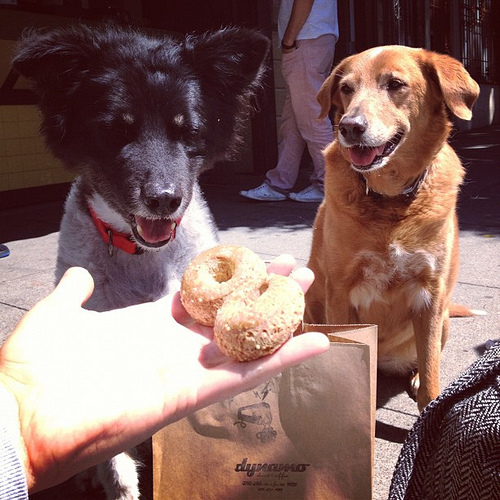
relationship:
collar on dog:
[86, 192, 146, 264] [5, 26, 255, 302]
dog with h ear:
[300, 44, 485, 412] [418, 47, 482, 127]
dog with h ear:
[300, 44, 485, 412] [312, 55, 342, 124]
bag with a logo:
[145, 322, 380, 498] [232, 401, 277, 444]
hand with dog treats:
[0, 249, 330, 486] [176, 233, 309, 365]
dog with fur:
[299, 41, 490, 426] [318, 147, 463, 389]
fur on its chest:
[318, 147, 463, 389] [349, 227, 452, 340]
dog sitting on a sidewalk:
[300, 44, 485, 412] [2, 147, 499, 499]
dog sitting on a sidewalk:
[0, 0, 229, 500] [2, 147, 499, 499]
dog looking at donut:
[1, 25, 225, 499] [212, 274, 309, 364]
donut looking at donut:
[172, 231, 312, 375] [180, 243, 264, 318]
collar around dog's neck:
[85, 201, 144, 256] [72, 160, 129, 230]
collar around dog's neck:
[359, 166, 430, 204] [358, 122, 451, 196]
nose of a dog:
[127, 171, 220, 224] [5, 26, 255, 302]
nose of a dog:
[333, 121, 376, 153] [320, 48, 467, 381]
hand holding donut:
[0, 249, 330, 486] [215, 276, 319, 361]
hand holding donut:
[0, 249, 330, 486] [176, 242, 265, 327]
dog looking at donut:
[300, 44, 485, 412] [176, 242, 265, 327]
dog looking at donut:
[300, 44, 485, 412] [212, 274, 309, 364]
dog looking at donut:
[0, 0, 229, 500] [176, 242, 265, 327]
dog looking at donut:
[0, 0, 229, 500] [210, 272, 318, 358]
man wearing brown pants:
[238, 0, 336, 202] [260, 32, 340, 200]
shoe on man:
[286, 184, 323, 206] [245, 2, 350, 218]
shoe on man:
[239, 184, 285, 204] [245, 2, 350, 218]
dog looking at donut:
[0, 0, 229, 500] [212, 274, 309, 364]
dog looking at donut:
[0, 0, 229, 500] [172, 243, 270, 329]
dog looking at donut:
[300, 44, 485, 412] [172, 243, 270, 329]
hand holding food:
[0, 249, 331, 484] [179, 246, 306, 360]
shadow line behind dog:
[1, 205, 499, 265] [299, 41, 490, 426]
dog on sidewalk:
[0, 0, 229, 500] [2, 147, 499, 499]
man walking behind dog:
[223, 3, 338, 207] [300, 44, 485, 412]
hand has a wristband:
[0, 249, 331, 484] [281, 37, 299, 52]